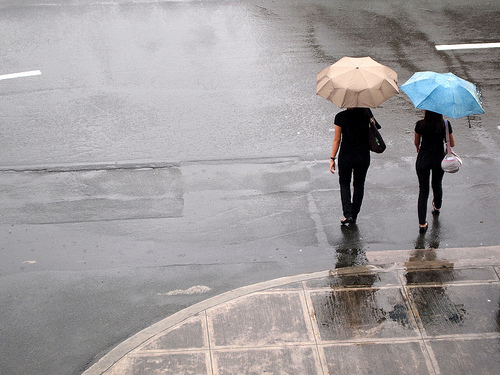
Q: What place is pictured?
A: It is a street.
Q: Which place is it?
A: It is a street.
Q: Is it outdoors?
A: Yes, it is outdoors.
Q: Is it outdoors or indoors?
A: It is outdoors.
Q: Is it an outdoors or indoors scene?
A: It is outdoors.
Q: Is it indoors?
A: No, it is outdoors.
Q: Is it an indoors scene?
A: No, it is outdoors.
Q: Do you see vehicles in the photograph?
A: No, there are no vehicles.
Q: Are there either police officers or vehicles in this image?
A: No, there are no vehicles or police officers.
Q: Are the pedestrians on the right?
A: Yes, the pedestrians are on the right of the image.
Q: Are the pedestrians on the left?
A: No, the pedestrians are on the right of the image.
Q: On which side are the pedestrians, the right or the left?
A: The pedestrians are on the right of the image.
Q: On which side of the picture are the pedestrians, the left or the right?
A: The pedestrians are on the right of the image.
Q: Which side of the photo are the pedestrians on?
A: The pedestrians are on the right of the image.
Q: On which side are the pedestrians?
A: The pedestrians are on the right of the image.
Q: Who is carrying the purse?
A: The pedestrians are carrying the purse.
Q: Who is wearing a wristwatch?
A: The pedestrians are wearing a wristwatch.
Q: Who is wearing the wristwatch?
A: The pedestrians are wearing a wristwatch.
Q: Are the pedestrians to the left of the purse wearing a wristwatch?
A: Yes, the pedestrians are wearing a wristwatch.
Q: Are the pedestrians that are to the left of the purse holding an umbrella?
A: Yes, the pedestrians are holding an umbrella.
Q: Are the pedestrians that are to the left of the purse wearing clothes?
A: Yes, the pedestrians are wearing clothes.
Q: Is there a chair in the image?
A: No, there are no chairs.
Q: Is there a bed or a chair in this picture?
A: No, there are no chairs or beds.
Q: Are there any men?
A: No, there are no men.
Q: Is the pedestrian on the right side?
A: Yes, the pedestrian is on the right of the image.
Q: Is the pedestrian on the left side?
A: No, the pedestrian is on the right of the image.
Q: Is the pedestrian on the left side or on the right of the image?
A: The pedestrian is on the right of the image.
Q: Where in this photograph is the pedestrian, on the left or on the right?
A: The pedestrian is on the right of the image.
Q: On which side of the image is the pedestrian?
A: The pedestrian is on the right of the image.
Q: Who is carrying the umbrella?
A: The pedestrian is carrying the umbrella.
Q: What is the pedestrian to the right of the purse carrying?
A: The pedestrian is carrying an umbrella.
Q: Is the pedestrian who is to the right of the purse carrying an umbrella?
A: Yes, the pedestrian is carrying an umbrella.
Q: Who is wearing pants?
A: The pedestrian is wearing pants.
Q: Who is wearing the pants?
A: The pedestrian is wearing pants.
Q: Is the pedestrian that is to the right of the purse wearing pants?
A: Yes, the pedestrian is wearing pants.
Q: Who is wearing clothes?
A: The pedestrian is wearing clothes.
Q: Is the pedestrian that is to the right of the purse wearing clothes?
A: Yes, the pedestrian is wearing clothes.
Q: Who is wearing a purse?
A: The pedestrian is wearing a purse.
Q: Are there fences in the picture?
A: No, there are no fences.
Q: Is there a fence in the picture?
A: No, there are no fences.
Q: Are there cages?
A: No, there are no cages.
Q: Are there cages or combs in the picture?
A: No, there are no cages or combs.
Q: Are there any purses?
A: Yes, there is a purse.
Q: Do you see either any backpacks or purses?
A: Yes, there is a purse.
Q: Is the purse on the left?
A: No, the purse is on the right of the image.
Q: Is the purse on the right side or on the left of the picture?
A: The purse is on the right of the image.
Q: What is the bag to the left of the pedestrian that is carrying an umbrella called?
A: The bag is a purse.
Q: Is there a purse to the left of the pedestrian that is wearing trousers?
A: Yes, there is a purse to the left of the pedestrian.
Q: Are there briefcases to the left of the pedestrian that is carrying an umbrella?
A: No, there is a purse to the left of the pedestrian.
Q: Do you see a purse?
A: Yes, there is a purse.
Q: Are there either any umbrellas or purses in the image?
A: Yes, there is a purse.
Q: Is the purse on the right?
A: Yes, the purse is on the right of the image.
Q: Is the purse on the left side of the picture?
A: No, the purse is on the right of the image.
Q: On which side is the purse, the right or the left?
A: The purse is on the right of the image.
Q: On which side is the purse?
A: The purse is on the right of the image.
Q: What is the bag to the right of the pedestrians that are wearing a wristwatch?
A: The bag is a purse.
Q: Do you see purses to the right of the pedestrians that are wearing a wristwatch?
A: Yes, there is a purse to the right of the pedestrians.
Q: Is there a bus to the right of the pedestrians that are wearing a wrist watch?
A: No, there is a purse to the right of the pedestrians.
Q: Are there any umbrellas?
A: Yes, there is an umbrella.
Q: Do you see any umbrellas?
A: Yes, there is an umbrella.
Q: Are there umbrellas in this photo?
A: Yes, there is an umbrella.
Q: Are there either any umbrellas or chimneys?
A: Yes, there is an umbrella.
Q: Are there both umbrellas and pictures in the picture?
A: No, there is an umbrella but no pictures.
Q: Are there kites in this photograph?
A: No, there are no kites.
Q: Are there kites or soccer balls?
A: No, there are no kites or soccer balls.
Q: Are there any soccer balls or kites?
A: No, there are no kites or soccer balls.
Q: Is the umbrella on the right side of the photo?
A: Yes, the umbrella is on the right of the image.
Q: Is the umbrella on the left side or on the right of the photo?
A: The umbrella is on the right of the image.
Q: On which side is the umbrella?
A: The umbrella is on the right of the image.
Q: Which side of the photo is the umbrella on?
A: The umbrella is on the right of the image.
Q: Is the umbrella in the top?
A: Yes, the umbrella is in the top of the image.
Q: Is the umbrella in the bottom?
A: No, the umbrella is in the top of the image.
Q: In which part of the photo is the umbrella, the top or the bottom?
A: The umbrella is in the top of the image.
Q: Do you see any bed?
A: No, there are no beds.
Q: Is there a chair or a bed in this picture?
A: No, there are no beds or chairs.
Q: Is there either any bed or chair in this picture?
A: No, there are no beds or chairs.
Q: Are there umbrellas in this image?
A: Yes, there is an umbrella.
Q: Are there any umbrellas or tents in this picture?
A: Yes, there is an umbrella.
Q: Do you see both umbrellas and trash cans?
A: No, there is an umbrella but no trash cans.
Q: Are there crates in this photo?
A: No, there are no crates.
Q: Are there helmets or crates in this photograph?
A: No, there are no crates or helmets.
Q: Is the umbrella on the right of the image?
A: Yes, the umbrella is on the right of the image.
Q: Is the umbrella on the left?
A: No, the umbrella is on the right of the image.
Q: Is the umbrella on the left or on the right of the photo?
A: The umbrella is on the right of the image.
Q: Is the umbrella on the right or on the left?
A: The umbrella is on the right of the image.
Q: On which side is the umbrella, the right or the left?
A: The umbrella is on the right of the image.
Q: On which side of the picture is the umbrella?
A: The umbrella is on the right of the image.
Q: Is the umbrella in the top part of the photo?
A: Yes, the umbrella is in the top of the image.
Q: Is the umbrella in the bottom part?
A: No, the umbrella is in the top of the image.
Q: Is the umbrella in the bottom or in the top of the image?
A: The umbrella is in the top of the image.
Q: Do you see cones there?
A: No, there are no cones.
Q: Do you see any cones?
A: No, there are no cones.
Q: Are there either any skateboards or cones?
A: No, there are no cones or skateboards.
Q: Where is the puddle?
A: The puddle is on the street.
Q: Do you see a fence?
A: No, there are no fences.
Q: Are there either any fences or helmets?
A: No, there are no fences or helmets.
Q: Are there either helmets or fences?
A: No, there are no fences or helmets.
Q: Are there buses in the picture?
A: No, there are no buses.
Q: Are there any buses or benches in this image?
A: No, there are no buses or benches.